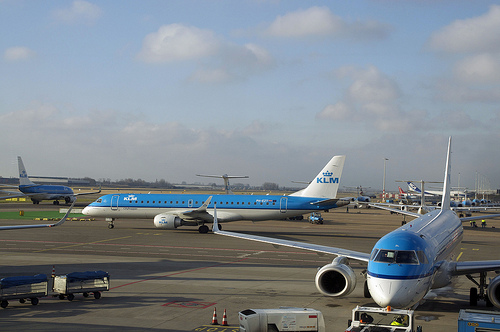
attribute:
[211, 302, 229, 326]
traffic cones — Orange, white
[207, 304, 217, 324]
traffic cone — Orange, white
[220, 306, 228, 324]
traffic cone — Orange, white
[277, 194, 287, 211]
door — passenger door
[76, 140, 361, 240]
plane — blue, white